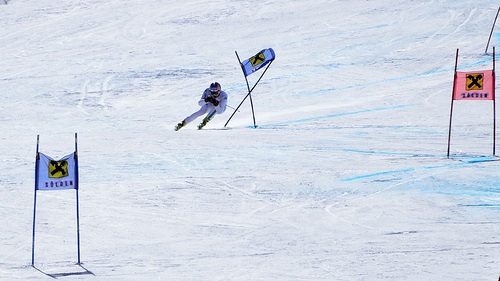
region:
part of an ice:
[382, 154, 401, 165]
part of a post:
[69, 184, 76, 192]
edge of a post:
[436, 118, 450, 125]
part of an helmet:
[217, 85, 225, 90]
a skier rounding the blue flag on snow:
[152, 30, 332, 157]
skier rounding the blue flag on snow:
[151, 60, 225, 137]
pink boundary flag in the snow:
[428, 37, 493, 179]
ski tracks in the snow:
[164, 145, 345, 250]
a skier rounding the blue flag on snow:
[139, 42, 385, 229]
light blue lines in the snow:
[340, 108, 440, 193]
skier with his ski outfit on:
[173, 68, 228, 138]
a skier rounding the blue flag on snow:
[24, 30, 489, 280]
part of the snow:
[381, 221, 406, 245]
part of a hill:
[272, 194, 287, 207]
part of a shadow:
[74, 263, 84, 279]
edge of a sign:
[241, 109, 256, 117]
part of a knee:
[191, 82, 204, 126]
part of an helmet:
[210, 65, 218, 99]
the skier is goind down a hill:
[172, 81, 231, 129]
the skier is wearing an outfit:
[188, 86, 225, 127]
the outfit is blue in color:
[183, 88, 226, 125]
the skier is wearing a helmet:
[208, 83, 221, 96]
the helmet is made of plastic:
[208, 81, 220, 93]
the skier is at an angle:
[173, 81, 230, 131]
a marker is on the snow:
[29, 125, 88, 263]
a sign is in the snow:
[38, 152, 78, 189]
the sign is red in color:
[453, 68, 498, 103]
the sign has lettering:
[461, 92, 487, 100]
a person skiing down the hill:
[176, 80, 232, 130]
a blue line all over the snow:
[301, 55, 493, 230]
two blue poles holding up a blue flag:
[24, 131, 89, 271]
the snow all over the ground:
[2, 3, 498, 269]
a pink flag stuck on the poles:
[439, 38, 499, 164]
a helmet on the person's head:
[206, 80, 221, 92]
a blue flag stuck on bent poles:
[223, 51, 272, 126]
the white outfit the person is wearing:
[185, 89, 228, 124]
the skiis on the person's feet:
[173, 120, 208, 130]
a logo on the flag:
[41, 157, 71, 182]